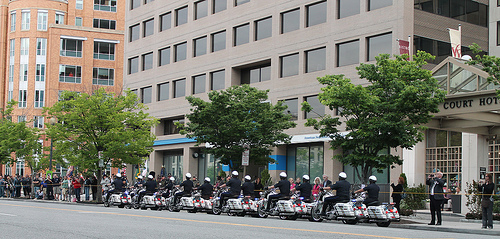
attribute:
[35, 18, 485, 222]
picture — taken, day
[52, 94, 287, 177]
trees — green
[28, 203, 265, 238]
street — gray, asphalt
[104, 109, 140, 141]
leaves — green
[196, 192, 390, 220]
motorcycles — black, white, many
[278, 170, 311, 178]
helmets — white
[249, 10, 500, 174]
building — court house, courthouse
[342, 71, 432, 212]
tree — green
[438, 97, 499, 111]
letters — black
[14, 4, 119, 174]
building — brick, orange, brown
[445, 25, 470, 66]
banner — white, red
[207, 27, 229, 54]
window — closed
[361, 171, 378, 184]
helmet — white